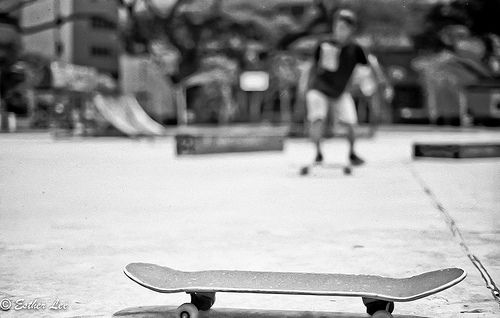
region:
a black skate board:
[122, 260, 462, 316]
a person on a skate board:
[291, 9, 391, 176]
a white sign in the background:
[239, 70, 270, 90]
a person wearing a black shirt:
[296, 9, 383, 173]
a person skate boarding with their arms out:
[296, 10, 381, 173]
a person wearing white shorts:
[293, 9, 378, 168]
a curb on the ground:
[173, 127, 289, 151]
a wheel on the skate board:
[176, 303, 195, 317]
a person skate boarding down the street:
[302, 12, 392, 174]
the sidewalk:
[1, 178, 497, 260]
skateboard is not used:
[125, 261, 456, 303]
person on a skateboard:
[305, 30, 357, 185]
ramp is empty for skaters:
[70, 65, 170, 140]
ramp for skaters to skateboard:
[91, 80, 156, 157]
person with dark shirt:
[320, 33, 360, 103]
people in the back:
[152, 21, 250, 69]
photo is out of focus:
[1, 4, 498, 159]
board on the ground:
[390, 140, 496, 160]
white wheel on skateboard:
[175, 300, 195, 316]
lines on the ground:
[415, 168, 489, 295]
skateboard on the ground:
[128, 253, 464, 316]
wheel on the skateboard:
[178, 303, 198, 315]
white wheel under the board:
[366, 303, 390, 316]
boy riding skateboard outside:
[259, 6, 409, 181]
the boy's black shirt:
[311, 41, 362, 93]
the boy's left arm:
[353, 47, 416, 105]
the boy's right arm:
[271, 32, 319, 72]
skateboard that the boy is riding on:
[290, 155, 372, 177]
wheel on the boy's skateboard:
[296, 163, 313, 178]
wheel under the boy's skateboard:
[346, 167, 355, 176]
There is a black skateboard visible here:
[203, 236, 322, 311]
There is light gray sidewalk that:
[55, 220, 71, 269]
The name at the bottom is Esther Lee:
[12, 286, 67, 314]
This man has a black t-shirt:
[322, 17, 376, 92]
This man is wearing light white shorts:
[310, 84, 362, 126]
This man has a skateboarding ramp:
[93, 87, 178, 167]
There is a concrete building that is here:
[71, 13, 121, 80]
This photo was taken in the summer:
[103, 45, 385, 297]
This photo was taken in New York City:
[124, 20, 374, 308]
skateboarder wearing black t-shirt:
[288, 7, 393, 179]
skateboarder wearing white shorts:
[291, 0, 393, 175]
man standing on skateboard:
[283, 11, 393, 177]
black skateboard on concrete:
[122, 259, 467, 316]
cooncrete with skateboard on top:
[0, 125, 498, 315]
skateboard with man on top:
[290, 161, 374, 173]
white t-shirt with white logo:
[297, 38, 369, 100]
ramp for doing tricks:
[412, 142, 499, 158]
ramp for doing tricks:
[174, 128, 285, 157]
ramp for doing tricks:
[93, 91, 169, 136]